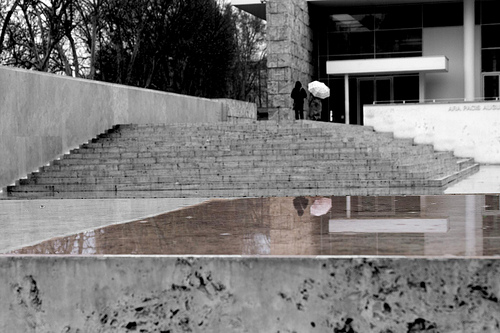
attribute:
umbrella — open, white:
[306, 78, 334, 100]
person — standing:
[291, 81, 307, 122]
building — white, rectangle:
[228, 2, 499, 117]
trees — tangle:
[5, 0, 265, 95]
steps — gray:
[6, 117, 485, 198]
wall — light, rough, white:
[360, 101, 500, 165]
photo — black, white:
[2, 1, 499, 333]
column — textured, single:
[265, 1, 318, 119]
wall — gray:
[2, 63, 227, 194]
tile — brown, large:
[17, 195, 499, 254]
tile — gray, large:
[3, 199, 215, 253]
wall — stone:
[219, 98, 259, 124]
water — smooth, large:
[35, 196, 500, 252]